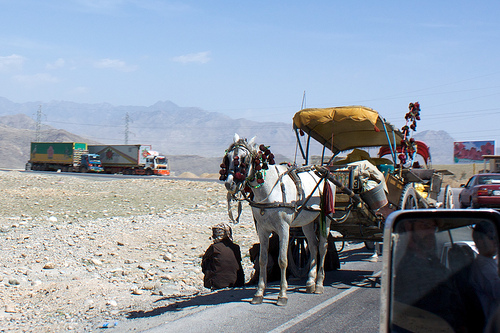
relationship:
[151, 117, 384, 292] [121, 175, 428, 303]
people sitting on side of road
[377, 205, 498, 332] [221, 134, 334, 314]
mirror next to horse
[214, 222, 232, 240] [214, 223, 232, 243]
rag on head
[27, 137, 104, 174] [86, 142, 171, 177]
truck driving side by side truck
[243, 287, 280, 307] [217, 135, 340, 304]
hoof on horse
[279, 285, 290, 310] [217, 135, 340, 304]
hoof on horse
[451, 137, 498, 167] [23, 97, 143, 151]
billboard on pole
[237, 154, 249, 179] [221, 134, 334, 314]
blinder on horse